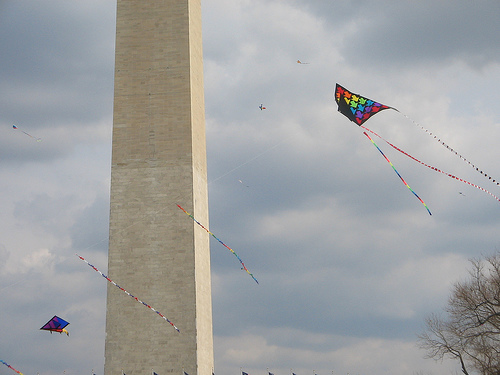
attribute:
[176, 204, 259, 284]
kite — blue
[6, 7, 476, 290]
skies — very cloudy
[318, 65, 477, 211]
kite — flying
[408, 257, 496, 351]
tree — bare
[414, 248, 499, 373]
branches — dry, dead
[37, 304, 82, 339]
kite — blue, big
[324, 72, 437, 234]
kite — flying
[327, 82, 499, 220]
kite — rainbow colred, blue, big, purple, red, yellow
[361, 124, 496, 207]
kite tail — red, blue, white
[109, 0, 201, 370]
tower — cream colored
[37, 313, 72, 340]
kite — big, blue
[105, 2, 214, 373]
monument — tall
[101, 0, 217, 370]
building — cream